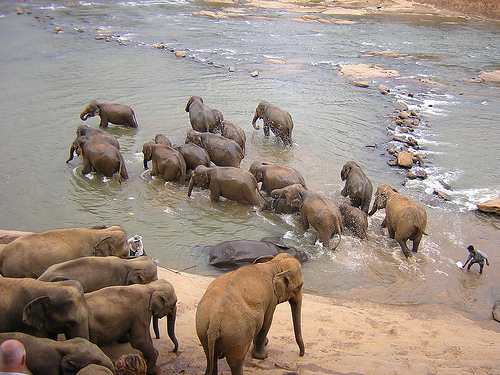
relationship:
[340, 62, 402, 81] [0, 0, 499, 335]
patch in water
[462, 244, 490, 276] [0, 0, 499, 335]
man taking water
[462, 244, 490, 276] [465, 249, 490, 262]
man wearing shirt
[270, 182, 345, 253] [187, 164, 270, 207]
elephant behind elephant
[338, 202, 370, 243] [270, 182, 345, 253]
elephant next to elephant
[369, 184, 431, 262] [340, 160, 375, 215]
elephant behind elephant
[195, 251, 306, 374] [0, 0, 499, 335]
elephant heading towards water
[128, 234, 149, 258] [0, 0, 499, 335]
man in water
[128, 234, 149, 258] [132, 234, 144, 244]
man wearing hat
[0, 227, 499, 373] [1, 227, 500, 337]
shore has edge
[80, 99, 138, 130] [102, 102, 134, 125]
elephant has body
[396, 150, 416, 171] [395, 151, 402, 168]
rock has edge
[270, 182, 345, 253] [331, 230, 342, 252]
elephant has tail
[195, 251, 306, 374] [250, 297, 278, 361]
elephant has leg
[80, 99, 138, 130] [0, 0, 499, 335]
elephant in water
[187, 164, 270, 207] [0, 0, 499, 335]
elephant in water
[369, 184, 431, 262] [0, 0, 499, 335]
elephant in water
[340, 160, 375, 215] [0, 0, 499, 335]
elephant in water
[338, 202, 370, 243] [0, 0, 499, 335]
elephant in water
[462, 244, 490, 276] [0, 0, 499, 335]
man in water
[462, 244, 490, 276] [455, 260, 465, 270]
man holding container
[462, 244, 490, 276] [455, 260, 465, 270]
man filling container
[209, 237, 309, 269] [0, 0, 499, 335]
elephant in water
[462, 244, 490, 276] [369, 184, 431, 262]
man behind elephant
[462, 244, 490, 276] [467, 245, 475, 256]
man has head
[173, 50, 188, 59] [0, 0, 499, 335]
stone in river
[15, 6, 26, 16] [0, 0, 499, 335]
stone in river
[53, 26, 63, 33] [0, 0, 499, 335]
stone in river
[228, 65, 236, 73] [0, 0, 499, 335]
stone in river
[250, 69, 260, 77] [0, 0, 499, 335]
stone in river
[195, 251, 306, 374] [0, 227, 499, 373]
elephant on shore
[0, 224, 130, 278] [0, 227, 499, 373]
elephant on shore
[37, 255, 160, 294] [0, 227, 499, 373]
elephant on shore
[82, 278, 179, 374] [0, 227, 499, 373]
elephant on shore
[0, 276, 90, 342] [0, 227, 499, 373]
elephant on shore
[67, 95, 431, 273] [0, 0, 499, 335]
group in water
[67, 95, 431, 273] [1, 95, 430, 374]
group of elephants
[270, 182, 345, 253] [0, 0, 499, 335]
elephant in water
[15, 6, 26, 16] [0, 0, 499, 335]
stone in water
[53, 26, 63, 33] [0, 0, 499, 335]
stone in water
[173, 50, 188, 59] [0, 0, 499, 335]
stone in water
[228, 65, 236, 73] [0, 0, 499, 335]
stone in water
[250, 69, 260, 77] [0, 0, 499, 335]
stone in water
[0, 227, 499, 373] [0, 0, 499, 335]
shore near water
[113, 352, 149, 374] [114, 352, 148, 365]
person has top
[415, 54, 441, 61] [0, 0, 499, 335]
object in water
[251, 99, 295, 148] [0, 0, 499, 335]
elephant in water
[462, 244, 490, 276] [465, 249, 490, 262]
man has shirt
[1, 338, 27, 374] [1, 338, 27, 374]
man has head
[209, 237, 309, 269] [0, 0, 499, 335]
elephant under water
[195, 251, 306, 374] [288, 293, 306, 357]
elephant has trunk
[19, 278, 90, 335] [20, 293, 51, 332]
head has ear